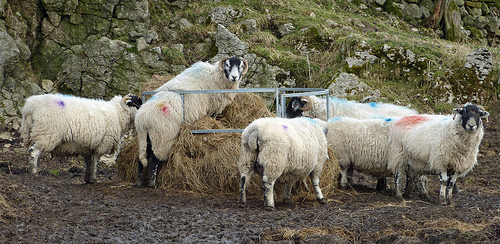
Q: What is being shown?
A: Sheep.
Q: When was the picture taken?
A: During the daytime.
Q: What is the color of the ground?
A: Brown.